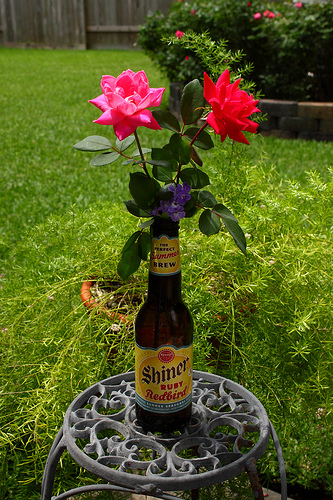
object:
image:
[1, 5, 330, 493]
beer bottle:
[132, 219, 195, 433]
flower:
[89, 69, 165, 142]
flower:
[200, 65, 262, 148]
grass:
[9, 53, 90, 136]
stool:
[30, 365, 287, 499]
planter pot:
[228, 88, 333, 149]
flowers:
[150, 206, 159, 218]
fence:
[3, 0, 145, 50]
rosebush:
[279, 8, 331, 94]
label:
[133, 338, 193, 415]